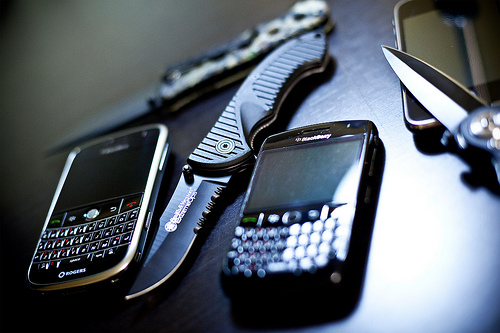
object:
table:
[5, 3, 495, 331]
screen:
[254, 143, 366, 215]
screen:
[404, 10, 495, 94]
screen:
[69, 145, 151, 204]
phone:
[390, 9, 498, 130]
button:
[62, 227, 70, 237]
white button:
[285, 234, 297, 246]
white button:
[86, 240, 98, 252]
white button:
[47, 230, 57, 241]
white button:
[306, 230, 322, 242]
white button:
[297, 255, 314, 271]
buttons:
[231, 223, 343, 279]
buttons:
[33, 200, 133, 271]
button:
[85, 206, 99, 214]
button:
[83, 221, 98, 233]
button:
[302, 220, 310, 234]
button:
[323, 230, 332, 242]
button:
[306, 245, 315, 255]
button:
[287, 234, 294, 243]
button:
[301, 257, 308, 266]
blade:
[378, 44, 499, 138]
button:
[108, 221, 120, 240]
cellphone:
[217, 119, 384, 297]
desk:
[81, 1, 496, 326]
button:
[106, 214, 119, 229]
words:
[167, 186, 194, 236]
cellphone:
[21, 127, 175, 291]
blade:
[121, 37, 329, 284]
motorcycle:
[325, 285, 337, 302]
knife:
[25, 1, 331, 137]